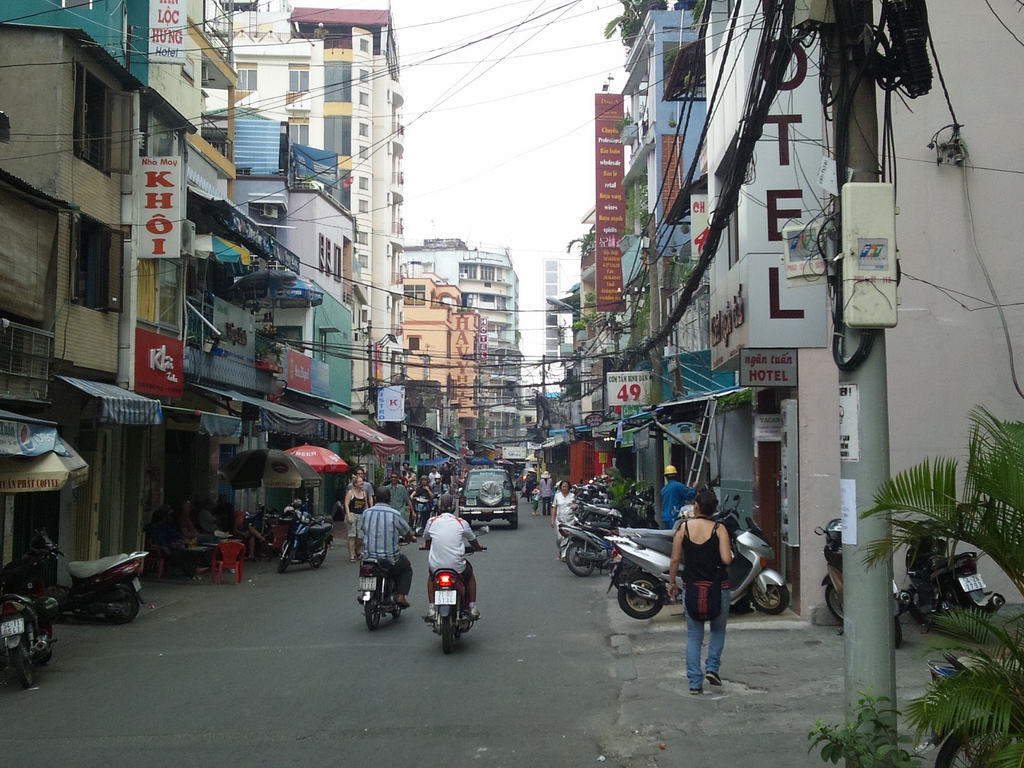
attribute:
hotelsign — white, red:
[738, 345, 806, 387]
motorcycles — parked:
[562, 499, 784, 617]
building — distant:
[390, 283, 482, 435]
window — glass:
[48, 202, 126, 343]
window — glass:
[39, 58, 96, 172]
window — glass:
[156, 255, 214, 355]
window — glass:
[140, 252, 160, 326]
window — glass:
[236, 72, 253, 93]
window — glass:
[276, 68, 318, 94]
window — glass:
[270, 116, 305, 164]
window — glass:
[309, 230, 345, 256]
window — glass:
[293, 226, 354, 290]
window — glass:
[362, 66, 379, 93]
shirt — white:
[422, 508, 479, 584]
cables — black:
[83, 7, 583, 306]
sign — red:
[586, 87, 638, 332]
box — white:
[818, 171, 911, 334]